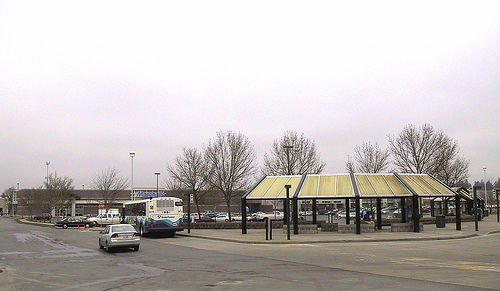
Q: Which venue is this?
A: This is a street.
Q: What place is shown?
A: It is a street.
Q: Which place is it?
A: It is a street.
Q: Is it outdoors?
A: Yes, it is outdoors.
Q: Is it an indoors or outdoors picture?
A: It is outdoors.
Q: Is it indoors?
A: No, it is outdoors.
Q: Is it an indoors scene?
A: No, it is outdoors.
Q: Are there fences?
A: No, there are no fences.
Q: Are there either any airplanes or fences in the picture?
A: No, there are no fences or airplanes.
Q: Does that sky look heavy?
A: Yes, the sky is heavy.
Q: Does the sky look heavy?
A: Yes, the sky is heavy.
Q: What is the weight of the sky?
A: The sky is heavy.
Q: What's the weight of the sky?
A: The sky is heavy.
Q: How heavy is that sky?
A: The sky is heavy.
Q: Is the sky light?
A: No, the sky is heavy.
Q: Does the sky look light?
A: No, the sky is heavy.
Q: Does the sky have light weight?
A: No, the sky is heavy.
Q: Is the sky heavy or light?
A: The sky is heavy.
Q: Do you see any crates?
A: No, there are no crates.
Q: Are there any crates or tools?
A: No, there are no crates or tools.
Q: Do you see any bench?
A: No, there are no benches.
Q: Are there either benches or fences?
A: No, there are no benches or fences.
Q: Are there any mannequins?
A: No, there are no mannequins.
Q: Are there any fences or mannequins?
A: No, there are no mannequins or fences.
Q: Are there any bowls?
A: No, there are no bowls.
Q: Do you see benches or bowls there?
A: No, there are no bowls or benches.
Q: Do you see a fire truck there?
A: No, there are no fire trucks.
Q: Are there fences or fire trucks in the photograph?
A: No, there are no fire trucks or fences.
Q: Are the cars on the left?
A: Yes, the cars are on the left of the image.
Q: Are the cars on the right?
A: No, the cars are on the left of the image.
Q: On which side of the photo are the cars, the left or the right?
A: The cars are on the left of the image.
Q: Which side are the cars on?
A: The cars are on the left of the image.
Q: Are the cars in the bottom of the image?
A: Yes, the cars are in the bottom of the image.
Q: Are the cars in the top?
A: No, the cars are in the bottom of the image.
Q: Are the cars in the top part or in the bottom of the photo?
A: The cars are in the bottom of the image.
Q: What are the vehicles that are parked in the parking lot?
A: The vehicles are cars.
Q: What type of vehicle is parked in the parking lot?
A: The vehicles are cars.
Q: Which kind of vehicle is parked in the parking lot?
A: The vehicles are cars.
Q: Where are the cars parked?
A: The cars are parked in the parking lot.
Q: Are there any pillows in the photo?
A: No, there are no pillows.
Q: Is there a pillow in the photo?
A: No, there are no pillows.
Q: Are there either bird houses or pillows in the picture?
A: No, there are no pillows or bird houses.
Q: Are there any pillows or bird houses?
A: No, there are no pillows or bird houses.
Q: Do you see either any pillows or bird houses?
A: No, there are no pillows or bird houses.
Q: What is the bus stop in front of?
A: The bus stop is in front of the trees.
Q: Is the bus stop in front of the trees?
A: Yes, the bus stop is in front of the trees.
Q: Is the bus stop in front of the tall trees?
A: Yes, the bus stop is in front of the trees.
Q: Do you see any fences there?
A: No, there are no fences.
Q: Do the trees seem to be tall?
A: Yes, the trees are tall.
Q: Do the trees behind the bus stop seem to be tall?
A: Yes, the trees are tall.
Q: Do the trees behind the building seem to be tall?
A: Yes, the trees are tall.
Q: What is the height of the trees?
A: The trees are tall.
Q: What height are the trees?
A: The trees are tall.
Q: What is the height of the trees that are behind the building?
A: The trees are tall.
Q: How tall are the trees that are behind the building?
A: The trees are tall.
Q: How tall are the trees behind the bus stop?
A: The trees are tall.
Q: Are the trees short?
A: No, the trees are tall.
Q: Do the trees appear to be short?
A: No, the trees are tall.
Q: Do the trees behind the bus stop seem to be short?
A: No, the trees are tall.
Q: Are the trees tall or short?
A: The trees are tall.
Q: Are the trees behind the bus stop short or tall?
A: The trees are tall.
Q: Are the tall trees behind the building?
A: Yes, the trees are behind the building.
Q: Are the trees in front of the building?
A: No, the trees are behind the building.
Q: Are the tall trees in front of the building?
A: No, the trees are behind the building.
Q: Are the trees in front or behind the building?
A: The trees are behind the building.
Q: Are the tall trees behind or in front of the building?
A: The trees are behind the building.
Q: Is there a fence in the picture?
A: No, there are no fences.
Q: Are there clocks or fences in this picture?
A: No, there are no fences or clocks.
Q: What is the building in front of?
A: The building is in front of the trees.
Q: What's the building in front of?
A: The building is in front of the trees.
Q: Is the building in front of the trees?
A: Yes, the building is in front of the trees.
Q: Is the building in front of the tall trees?
A: Yes, the building is in front of the trees.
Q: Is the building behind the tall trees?
A: No, the building is in front of the trees.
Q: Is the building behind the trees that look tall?
A: No, the building is in front of the trees.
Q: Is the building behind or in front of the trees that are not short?
A: The building is in front of the trees.